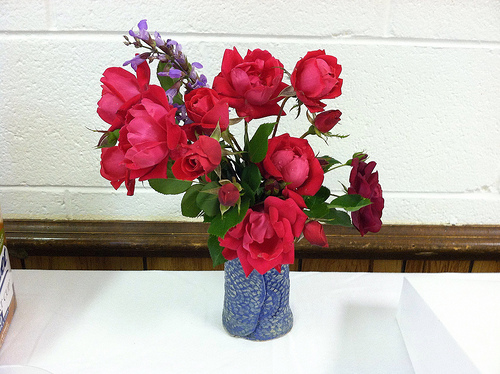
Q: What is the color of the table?
A: White.